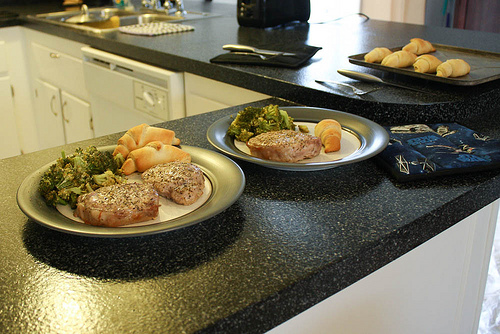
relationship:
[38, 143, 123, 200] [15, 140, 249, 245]
vegetables in plate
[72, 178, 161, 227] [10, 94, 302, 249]
meat on plate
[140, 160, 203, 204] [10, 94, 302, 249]
meat on plate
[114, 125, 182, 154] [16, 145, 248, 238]
crescent roll on plate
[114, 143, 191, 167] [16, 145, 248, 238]
crescent roll on plate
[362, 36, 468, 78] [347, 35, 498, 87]
croissants on pan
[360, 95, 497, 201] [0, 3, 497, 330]
mitt on counter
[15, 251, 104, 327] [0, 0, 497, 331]
glare on countertop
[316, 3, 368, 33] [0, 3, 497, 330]
cord from counter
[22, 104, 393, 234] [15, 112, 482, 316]
plates on counter